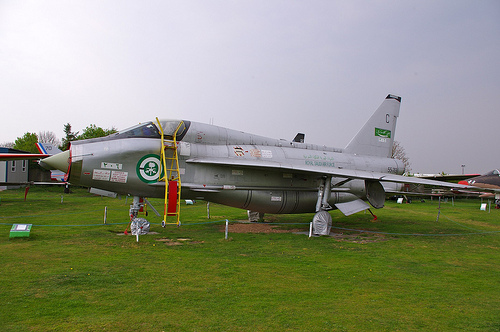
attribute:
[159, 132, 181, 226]
ladder — yellow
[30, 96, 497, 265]
jet — retired, on display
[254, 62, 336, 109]
sky — grey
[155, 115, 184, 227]
ladder — yellow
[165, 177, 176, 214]
panel — red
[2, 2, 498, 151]
sky — white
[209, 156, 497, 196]
wing — silver 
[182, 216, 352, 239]
patch — brown 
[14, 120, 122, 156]
trees — green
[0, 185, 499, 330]
grass — green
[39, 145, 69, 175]
nose — pointed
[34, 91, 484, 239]
plane — small, grey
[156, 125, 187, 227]
ladder — yellow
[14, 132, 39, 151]
leaves — green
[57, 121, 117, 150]
leaves — green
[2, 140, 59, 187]
building — white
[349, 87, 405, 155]
tail fin — silver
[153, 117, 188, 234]
ladder — yellow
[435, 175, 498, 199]
plane — red